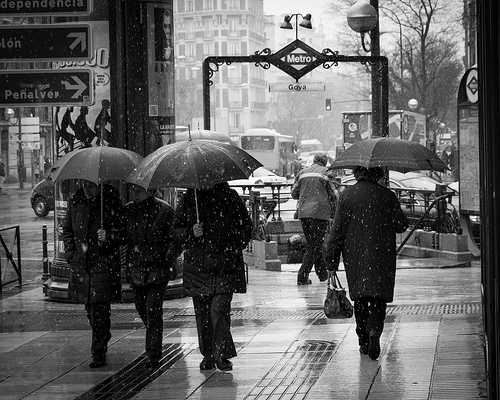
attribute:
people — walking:
[42, 117, 447, 307]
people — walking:
[188, 129, 387, 257]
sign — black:
[243, 11, 389, 106]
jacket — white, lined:
[281, 164, 341, 224]